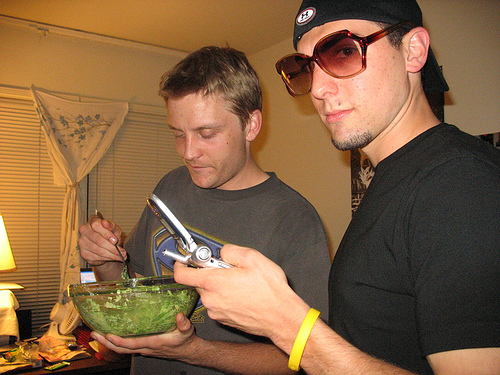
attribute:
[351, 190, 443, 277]
shirt — gray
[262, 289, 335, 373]
bracelet — yellow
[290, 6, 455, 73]
cap — black, backwards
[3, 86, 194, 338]
blinds — white, metal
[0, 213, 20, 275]
lamp — on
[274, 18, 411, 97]
sunglasses — brown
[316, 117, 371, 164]
hair — black facial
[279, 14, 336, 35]
logo — white, embroidered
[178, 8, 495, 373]
men — young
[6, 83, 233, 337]
windows — curtain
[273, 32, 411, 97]
sunglasses — brown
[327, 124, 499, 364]
black shirt — short sleeved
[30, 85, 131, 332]
curtain — white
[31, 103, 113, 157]
flowers — blue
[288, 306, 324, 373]
yellow bracelet — rubber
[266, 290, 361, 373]
band — yellow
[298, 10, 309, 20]
print — black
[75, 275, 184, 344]
guacamole — green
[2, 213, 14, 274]
shade —  white,  lamp's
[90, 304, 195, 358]
hand —  guy's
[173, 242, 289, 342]
hand —  guy's